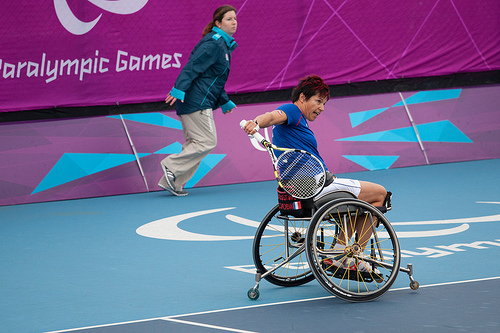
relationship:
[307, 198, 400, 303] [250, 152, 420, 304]
wheel on womans wheelchair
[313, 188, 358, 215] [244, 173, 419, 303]
part of a wheelchair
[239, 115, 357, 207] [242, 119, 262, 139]
racket in hand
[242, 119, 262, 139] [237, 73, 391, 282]
hand of woman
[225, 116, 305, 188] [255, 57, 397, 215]
shirt on woman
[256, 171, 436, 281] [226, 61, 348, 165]
wheelchair with woman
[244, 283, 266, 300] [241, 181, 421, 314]
stabilizing wheel on wheelchair